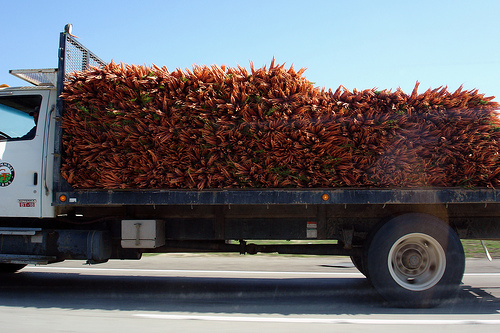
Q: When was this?
A: Daytime.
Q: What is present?
A: A truck.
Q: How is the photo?
A: Clear.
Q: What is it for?
A: Transport.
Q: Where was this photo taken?
A: On a street.